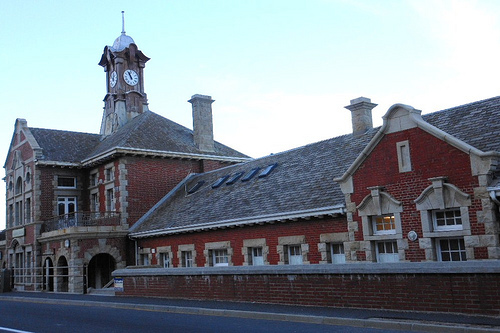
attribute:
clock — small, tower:
[96, 67, 156, 92]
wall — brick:
[110, 262, 497, 322]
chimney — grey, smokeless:
[184, 89, 225, 161]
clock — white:
[121, 67, 140, 87]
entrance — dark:
[71, 244, 123, 300]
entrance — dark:
[49, 253, 82, 290]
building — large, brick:
[63, 54, 422, 287]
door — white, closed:
[55, 192, 76, 223]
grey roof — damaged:
[208, 167, 335, 203]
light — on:
[368, 209, 417, 232]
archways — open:
[36, 241, 127, 291]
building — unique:
[7, 26, 499, 325]